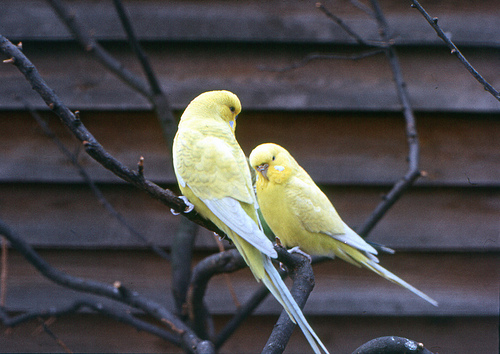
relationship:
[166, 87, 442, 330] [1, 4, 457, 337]
birds on branch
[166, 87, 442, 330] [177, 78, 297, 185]
birds have heads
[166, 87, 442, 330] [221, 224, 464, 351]
birds have tails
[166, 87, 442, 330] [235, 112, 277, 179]
birds have beaks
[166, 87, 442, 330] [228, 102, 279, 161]
birds have eyes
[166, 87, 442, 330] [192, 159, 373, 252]
birds have wings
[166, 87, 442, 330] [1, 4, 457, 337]
birds in branch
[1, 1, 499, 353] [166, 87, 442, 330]
building behind birds